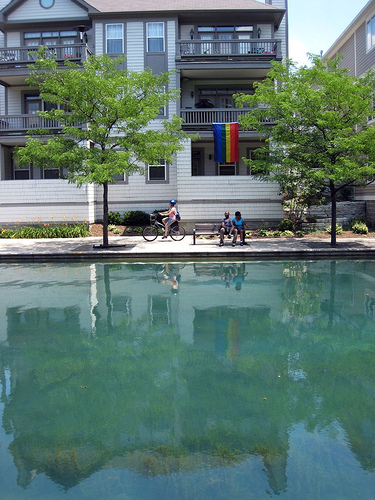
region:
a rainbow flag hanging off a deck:
[209, 122, 245, 169]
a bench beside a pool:
[189, 218, 251, 248]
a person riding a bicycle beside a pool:
[142, 197, 192, 246]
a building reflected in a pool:
[1, 259, 372, 497]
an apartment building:
[0, 1, 306, 239]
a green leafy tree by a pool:
[39, 55, 156, 258]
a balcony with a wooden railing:
[175, 13, 291, 66]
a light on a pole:
[74, 21, 97, 58]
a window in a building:
[134, 18, 170, 55]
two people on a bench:
[216, 207, 256, 250]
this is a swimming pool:
[98, 279, 353, 394]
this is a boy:
[158, 201, 180, 240]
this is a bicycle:
[148, 215, 156, 238]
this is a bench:
[190, 215, 213, 242]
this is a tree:
[66, 62, 149, 192]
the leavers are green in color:
[90, 148, 125, 174]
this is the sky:
[303, 4, 341, 31]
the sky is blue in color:
[312, 3, 324, 28]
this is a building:
[179, 18, 241, 93]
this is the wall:
[193, 181, 241, 200]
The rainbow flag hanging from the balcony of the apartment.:
[212, 122, 242, 164]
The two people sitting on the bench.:
[218, 207, 250, 243]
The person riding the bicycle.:
[153, 196, 181, 234]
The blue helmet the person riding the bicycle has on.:
[167, 195, 177, 204]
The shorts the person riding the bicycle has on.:
[160, 211, 174, 226]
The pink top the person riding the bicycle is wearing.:
[163, 207, 176, 219]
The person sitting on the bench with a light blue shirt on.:
[231, 216, 244, 230]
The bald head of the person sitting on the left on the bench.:
[222, 210, 231, 216]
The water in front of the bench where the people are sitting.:
[6, 258, 367, 497]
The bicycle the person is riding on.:
[140, 213, 185, 239]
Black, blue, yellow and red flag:
[211, 120, 241, 165]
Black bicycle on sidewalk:
[138, 210, 183, 241]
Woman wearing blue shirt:
[231, 208, 248, 245]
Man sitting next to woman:
[212, 205, 234, 242]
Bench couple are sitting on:
[187, 217, 244, 241]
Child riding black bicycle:
[151, 195, 178, 242]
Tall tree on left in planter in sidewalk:
[7, 150, 180, 255]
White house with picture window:
[1, 151, 356, 222]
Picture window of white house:
[185, 151, 276, 177]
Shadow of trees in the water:
[2, 300, 372, 490]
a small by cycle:
[146, 191, 189, 249]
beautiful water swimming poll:
[7, 261, 365, 493]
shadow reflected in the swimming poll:
[14, 311, 352, 488]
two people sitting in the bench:
[208, 203, 264, 241]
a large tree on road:
[37, 107, 137, 253]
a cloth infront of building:
[202, 114, 247, 179]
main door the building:
[194, 138, 260, 176]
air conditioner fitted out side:
[137, 154, 174, 192]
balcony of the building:
[174, 33, 279, 61]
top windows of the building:
[97, 25, 172, 61]